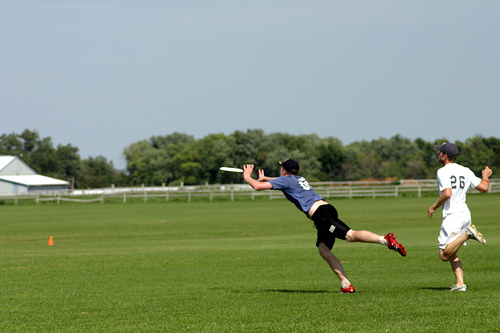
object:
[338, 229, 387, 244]
leg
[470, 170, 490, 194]
arm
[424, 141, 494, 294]
man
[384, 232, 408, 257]
shoe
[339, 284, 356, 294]
shoe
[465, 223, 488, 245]
shoe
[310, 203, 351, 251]
shorts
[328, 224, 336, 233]
logo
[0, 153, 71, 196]
builing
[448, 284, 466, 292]
shoe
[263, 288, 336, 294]
shadow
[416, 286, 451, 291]
shadow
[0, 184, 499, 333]
grass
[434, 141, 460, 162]
head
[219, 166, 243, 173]
frisbee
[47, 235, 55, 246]
cone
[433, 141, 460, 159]
hat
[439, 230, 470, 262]
leg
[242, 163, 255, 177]
hand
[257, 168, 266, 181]
hand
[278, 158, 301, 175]
hat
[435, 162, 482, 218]
shirt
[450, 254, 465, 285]
leg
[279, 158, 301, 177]
head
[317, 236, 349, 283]
leg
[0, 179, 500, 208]
wooden fence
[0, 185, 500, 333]
field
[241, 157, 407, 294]
man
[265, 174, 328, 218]
shirt